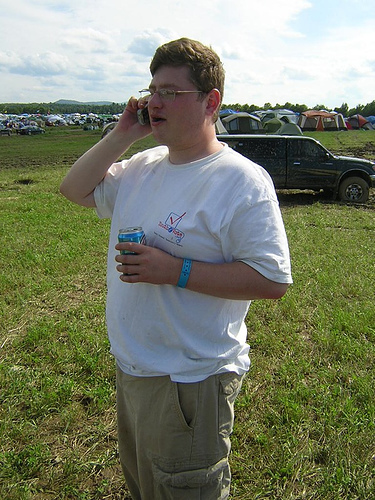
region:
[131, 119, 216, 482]
a man in white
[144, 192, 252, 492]
a man in white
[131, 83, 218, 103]
A PAIR OF GLASSES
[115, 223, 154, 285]
A CAN OF SODA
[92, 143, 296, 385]
A WHITE TEE SHIRT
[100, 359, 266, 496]
A PAIR OF PANTS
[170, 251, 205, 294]
A BLUE WRIST BAND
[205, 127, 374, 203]
A BLACK TRUCK ON THE GRASS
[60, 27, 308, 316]
A MAN TALKING ON A CELL PHONE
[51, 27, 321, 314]
A MAN HOLDING A CAN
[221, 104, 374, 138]
TENTS ON THE GRASS IN THE BACKGROUND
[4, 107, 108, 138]
CARS PARKED IN THE DISTANCE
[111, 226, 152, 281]
soda can on left hand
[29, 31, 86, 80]
Clouds are white color.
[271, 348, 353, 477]
Grass is green and brown color.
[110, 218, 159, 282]
Man is holding blue color can.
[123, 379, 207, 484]
Man is wearing tan color pant.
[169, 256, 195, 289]
Man is wearing blue color watch.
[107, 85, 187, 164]
Man is talking in the cell phone.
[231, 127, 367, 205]
Green car is parked behind the man.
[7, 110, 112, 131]
Cars are parked in the parking lot.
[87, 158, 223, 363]
Man is wearing white shirt.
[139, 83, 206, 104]
Man is wearing eye glass.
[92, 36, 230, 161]
A man is holding a cellphone.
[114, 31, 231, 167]
A man is talking on a cellphone.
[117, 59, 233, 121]
A man is wearing glasses.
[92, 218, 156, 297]
A man is holding a can.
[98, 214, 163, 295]
The color of a can is blue and silver.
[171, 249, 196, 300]
A man is wearing a wristband.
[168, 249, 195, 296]
The color of a wristband is blue.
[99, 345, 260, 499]
The color of a man's pants is tan.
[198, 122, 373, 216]
A vehicle is parked behind a man.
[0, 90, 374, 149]
A group of tents are in the background.